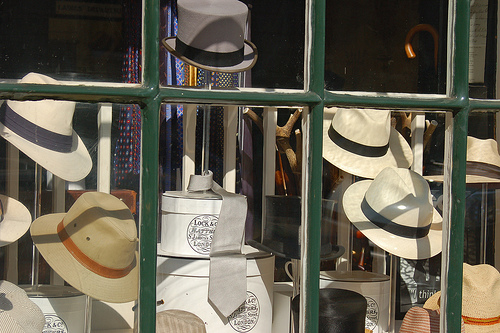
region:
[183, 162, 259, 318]
THE TIE IS GREY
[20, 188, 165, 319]
THE HAT HAS A BROWN BAND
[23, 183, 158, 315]
THE HAT IS TAN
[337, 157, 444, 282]
THE HAT HAS A BLACK BAND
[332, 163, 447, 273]
THE HAT IS WHITE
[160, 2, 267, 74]
THIS IS A TOP HAT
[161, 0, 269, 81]
THE TOP HAT HAS A BLACK BAND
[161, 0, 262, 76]
THE HAT IS GREY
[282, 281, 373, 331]
THE TOP HAT IS BLACK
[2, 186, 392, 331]
THE HAT BOXES ARE IN THE WINDOW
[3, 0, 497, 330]
Quaint, old-style, hat shop paned wood and glass shop window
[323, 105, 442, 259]
Two light beige hats with black hat-bands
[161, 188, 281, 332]
Stacked multi-sized hat boxes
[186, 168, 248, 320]
Men's tie wrapped about a chrome display pole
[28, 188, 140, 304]
Light brown hat with chocolate colored band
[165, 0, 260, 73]
Gray top-hat with black band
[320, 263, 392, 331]
Black hat in front of hat box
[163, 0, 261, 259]
Hat display with hatbox, tie, chrome pole stand and top-hat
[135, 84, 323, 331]
Green-framed glass window pane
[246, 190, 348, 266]
Shiny, black, satin top-hat through wooden paned store window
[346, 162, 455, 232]
this is a hat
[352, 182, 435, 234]
the hat is white in color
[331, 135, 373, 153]
this is a black strip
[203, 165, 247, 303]
this is a neck tie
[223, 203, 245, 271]
the tie is white in color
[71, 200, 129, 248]
the hat is brown in color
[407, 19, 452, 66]
this is a walking stick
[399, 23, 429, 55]
the walking stick is wooden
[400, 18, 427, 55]
the walking stick is brown in color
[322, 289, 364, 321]
the hat is black in color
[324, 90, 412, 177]
hat in the window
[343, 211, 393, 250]
shadow on the hat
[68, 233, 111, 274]
brown strap around hat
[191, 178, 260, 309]
tie in the window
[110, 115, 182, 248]
green rim of window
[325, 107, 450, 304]
two similar looking hats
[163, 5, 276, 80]
top hat in the photo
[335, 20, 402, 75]
dark background of the photo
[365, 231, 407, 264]
rim of the hat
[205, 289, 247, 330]
end of the tie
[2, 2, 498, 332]
articles of clothing seen through window panels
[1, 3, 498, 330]
window trim is dark green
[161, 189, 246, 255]
a small hat box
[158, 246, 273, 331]
a large hat box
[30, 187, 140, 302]
a hat with two small holes in its side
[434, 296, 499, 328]
orange band around a hat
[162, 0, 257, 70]
a grey top hat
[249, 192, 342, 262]
a black top hat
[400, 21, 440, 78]
a curved wooden handle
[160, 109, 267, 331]
a grey tie looped around a pole and draped over two hat boxes